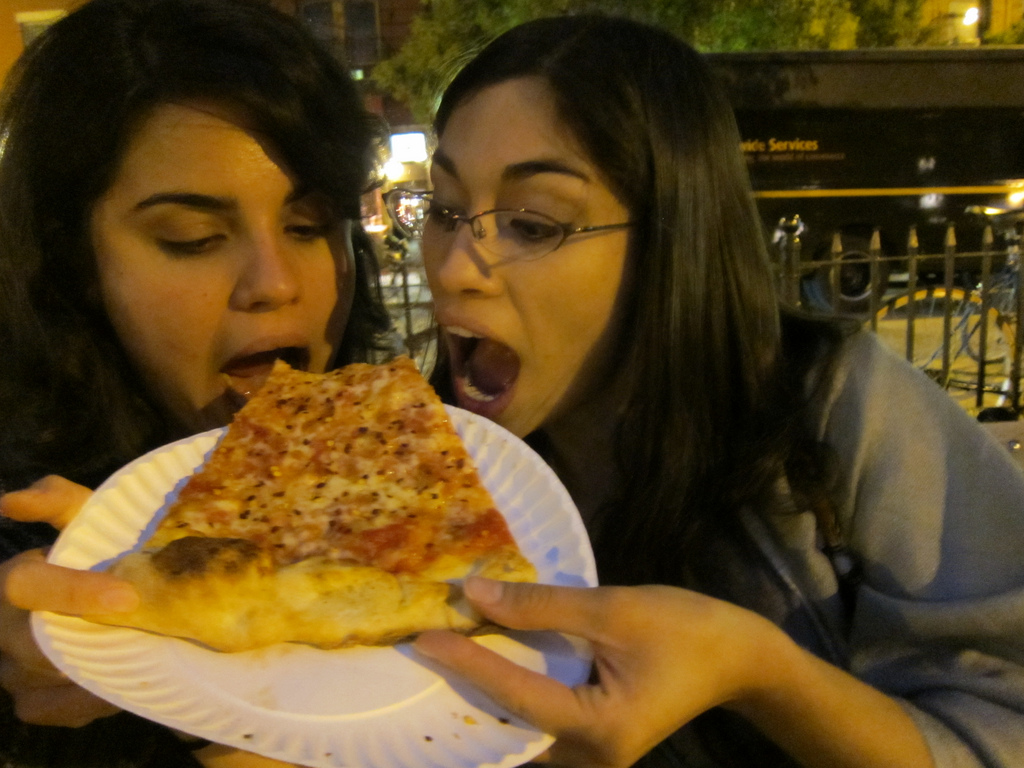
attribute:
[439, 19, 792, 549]
hair — black, long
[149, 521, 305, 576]
topping — black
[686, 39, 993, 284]
van — black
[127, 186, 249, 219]
eyebrow — black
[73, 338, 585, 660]
slice — large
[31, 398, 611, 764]
plate — white, paper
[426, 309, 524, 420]
mouth — opened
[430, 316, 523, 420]
mouth — opened, very wide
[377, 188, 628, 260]
eyeglasses — wire frame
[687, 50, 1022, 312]
vehicle — black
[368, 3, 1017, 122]
trees — green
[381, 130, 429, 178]
light — bright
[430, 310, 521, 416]
mouth — open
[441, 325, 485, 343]
teeth — white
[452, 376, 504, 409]
teeth — white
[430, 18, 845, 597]
hair — dark, brown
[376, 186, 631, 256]
glasses — thin, framed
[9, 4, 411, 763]
woman — dark haired